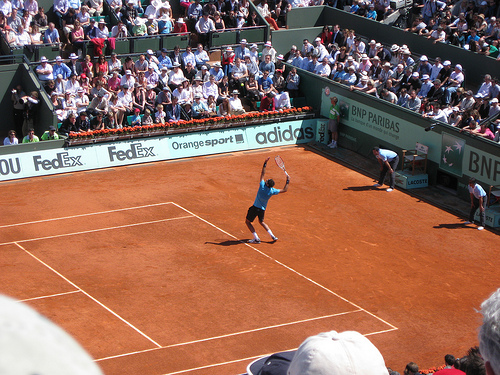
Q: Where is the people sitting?
A: In the stands.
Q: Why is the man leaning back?
A: To tap the ball.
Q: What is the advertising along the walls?
A: Fedex,orange sport and adidas.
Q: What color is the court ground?
A: A brown.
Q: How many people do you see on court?
A: Only four.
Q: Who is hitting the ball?
A: The man.